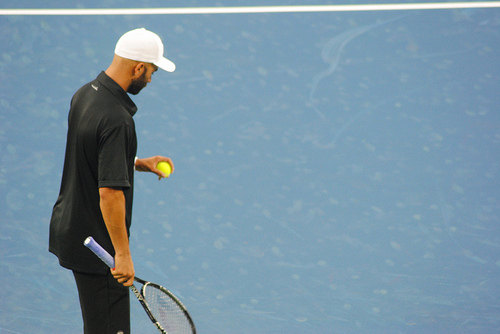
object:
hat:
[113, 25, 177, 73]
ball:
[156, 163, 171, 178]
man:
[48, 28, 176, 334]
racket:
[82, 235, 196, 334]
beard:
[127, 67, 147, 95]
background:
[1, 1, 498, 334]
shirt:
[48, 72, 139, 275]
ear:
[134, 62, 145, 77]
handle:
[83, 236, 116, 270]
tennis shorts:
[72, 269, 132, 334]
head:
[114, 28, 174, 94]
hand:
[134, 156, 175, 178]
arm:
[95, 111, 135, 256]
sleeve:
[99, 130, 132, 188]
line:
[1, 3, 498, 16]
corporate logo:
[157, 295, 185, 330]